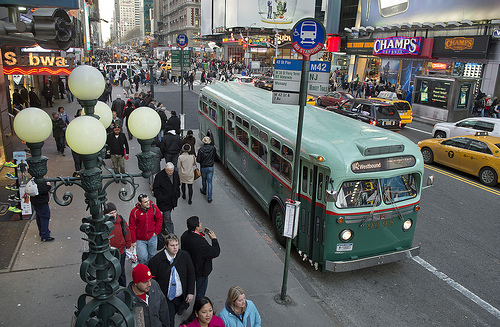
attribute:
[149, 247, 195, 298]
jacket — black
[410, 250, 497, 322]
line — white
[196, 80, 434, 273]
bus — green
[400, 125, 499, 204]
taxi — yellow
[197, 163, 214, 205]
jeans — blue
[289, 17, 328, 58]
sign — blue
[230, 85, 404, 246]
bus — two-tone, green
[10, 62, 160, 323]
lamp — white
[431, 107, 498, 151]
car — white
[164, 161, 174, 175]
white head — haired 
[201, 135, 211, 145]
white head — haired 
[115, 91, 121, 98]
white head — haired 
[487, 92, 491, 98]
white head — haired 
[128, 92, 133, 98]
white head — haired 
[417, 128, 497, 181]
cab — yellow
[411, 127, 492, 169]
car — yellow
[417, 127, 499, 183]
taxi — yellow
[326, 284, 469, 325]
tarmacked road — grey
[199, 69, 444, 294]
bus — green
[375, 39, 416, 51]
letters — white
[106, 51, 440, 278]
street — busy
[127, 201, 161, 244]
jacket — red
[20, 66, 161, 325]
light pole — green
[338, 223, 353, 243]
head light — small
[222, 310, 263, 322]
jacket — blue 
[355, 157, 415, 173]
sign — white 